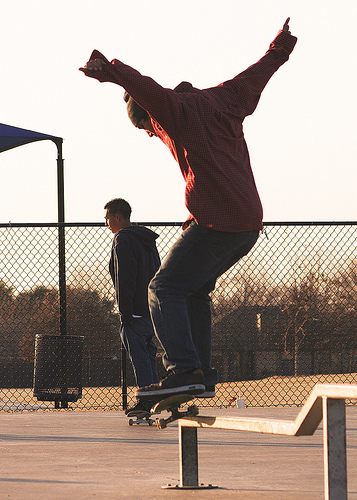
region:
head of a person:
[122, 78, 193, 137]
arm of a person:
[228, 26, 310, 106]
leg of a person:
[133, 230, 216, 388]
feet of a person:
[142, 379, 206, 403]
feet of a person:
[156, 383, 225, 426]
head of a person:
[102, 188, 144, 243]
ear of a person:
[110, 210, 122, 228]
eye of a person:
[95, 212, 118, 223]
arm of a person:
[106, 240, 146, 345]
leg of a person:
[118, 312, 150, 392]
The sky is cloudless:
[0, 2, 354, 206]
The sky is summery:
[3, 1, 347, 216]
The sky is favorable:
[7, 3, 349, 207]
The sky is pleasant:
[3, 3, 344, 207]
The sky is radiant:
[4, 3, 352, 204]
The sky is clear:
[5, 3, 350, 209]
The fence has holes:
[2, 217, 355, 423]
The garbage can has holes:
[18, 319, 103, 411]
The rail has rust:
[173, 411, 318, 448]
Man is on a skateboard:
[120, 48, 347, 410]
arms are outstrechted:
[90, 41, 337, 97]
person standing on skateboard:
[106, 215, 141, 427]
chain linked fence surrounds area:
[255, 228, 345, 383]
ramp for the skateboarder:
[176, 388, 356, 496]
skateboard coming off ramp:
[147, 389, 215, 428]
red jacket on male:
[146, 97, 277, 235]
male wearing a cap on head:
[121, 93, 140, 115]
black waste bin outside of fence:
[26, 328, 81, 412]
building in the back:
[216, 308, 353, 371]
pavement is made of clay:
[0, 422, 161, 492]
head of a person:
[118, 76, 153, 139]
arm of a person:
[98, 46, 171, 110]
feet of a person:
[122, 376, 221, 416]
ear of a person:
[112, 203, 132, 227]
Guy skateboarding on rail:
[75, 16, 297, 427]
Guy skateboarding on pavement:
[102, 196, 158, 420]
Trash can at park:
[31, 331, 78, 404]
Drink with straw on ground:
[228, 388, 244, 402]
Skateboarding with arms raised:
[77, 14, 293, 427]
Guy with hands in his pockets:
[102, 197, 162, 424]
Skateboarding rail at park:
[161, 381, 355, 498]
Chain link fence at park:
[0, 223, 355, 412]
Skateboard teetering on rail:
[149, 392, 197, 429]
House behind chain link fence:
[213, 303, 354, 381]